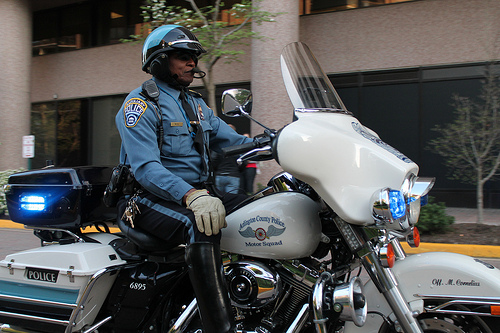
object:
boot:
[182, 242, 235, 333]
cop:
[112, 23, 273, 333]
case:
[1, 164, 109, 225]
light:
[20, 195, 45, 211]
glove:
[185, 189, 227, 236]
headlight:
[370, 173, 420, 222]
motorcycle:
[0, 87, 500, 333]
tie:
[179, 91, 208, 175]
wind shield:
[279, 40, 353, 115]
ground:
[0, 206, 500, 333]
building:
[0, 0, 498, 257]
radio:
[141, 79, 160, 101]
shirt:
[115, 75, 255, 206]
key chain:
[129, 187, 144, 202]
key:
[134, 202, 141, 214]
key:
[125, 217, 128, 221]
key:
[120, 210, 127, 220]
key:
[126, 211, 135, 229]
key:
[132, 199, 135, 220]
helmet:
[139, 23, 207, 88]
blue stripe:
[133, 195, 195, 245]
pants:
[117, 185, 225, 246]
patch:
[123, 98, 148, 128]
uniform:
[111, 75, 259, 333]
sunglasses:
[170, 47, 208, 61]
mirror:
[220, 88, 253, 118]